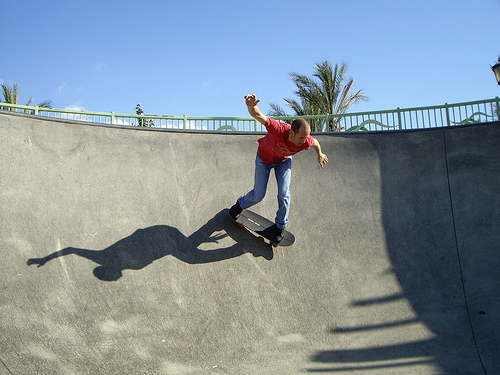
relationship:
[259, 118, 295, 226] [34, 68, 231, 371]
skater in skate park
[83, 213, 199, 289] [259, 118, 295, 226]
shadow of skater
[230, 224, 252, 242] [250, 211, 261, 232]
shadow of skate board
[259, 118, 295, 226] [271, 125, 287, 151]
skater wearing t-shirt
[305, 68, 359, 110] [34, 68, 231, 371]
plant in skate park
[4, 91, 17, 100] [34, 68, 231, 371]
plant in skate park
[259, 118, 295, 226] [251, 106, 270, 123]
skater has arm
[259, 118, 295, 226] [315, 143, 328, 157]
skater has arm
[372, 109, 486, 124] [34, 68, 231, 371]
fence around skate park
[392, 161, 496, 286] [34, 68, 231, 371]
shadow on skate park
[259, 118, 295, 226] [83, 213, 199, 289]
skater casting shadow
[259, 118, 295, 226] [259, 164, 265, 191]
skater wearing jeans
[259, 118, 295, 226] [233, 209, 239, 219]
skater has shoe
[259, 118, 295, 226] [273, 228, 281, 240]
skater has shoe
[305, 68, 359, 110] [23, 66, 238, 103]
plant in background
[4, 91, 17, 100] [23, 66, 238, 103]
plant in background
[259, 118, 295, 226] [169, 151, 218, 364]
skater riding ramp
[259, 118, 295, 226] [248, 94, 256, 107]
skater has hand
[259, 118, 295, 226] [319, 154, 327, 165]
skater has hand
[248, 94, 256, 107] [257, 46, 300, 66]
hand in air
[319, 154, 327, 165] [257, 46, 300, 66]
hand in air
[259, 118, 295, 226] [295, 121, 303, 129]
skater has hair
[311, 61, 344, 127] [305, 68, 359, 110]
frond of plant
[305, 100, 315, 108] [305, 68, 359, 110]
frond of plant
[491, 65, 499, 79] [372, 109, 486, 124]
street light near fence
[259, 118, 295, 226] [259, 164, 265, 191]
skater in jeans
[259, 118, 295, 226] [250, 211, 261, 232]
skater on skate board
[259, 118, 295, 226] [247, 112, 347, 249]
skater doing stunt